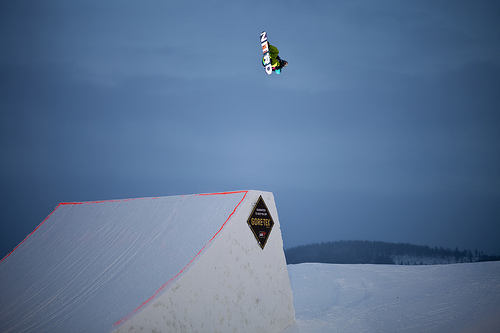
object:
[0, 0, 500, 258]
blue sky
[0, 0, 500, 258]
cloud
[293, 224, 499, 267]
trees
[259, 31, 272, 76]
snowboard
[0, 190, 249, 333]
square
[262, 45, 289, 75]
man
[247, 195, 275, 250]
sign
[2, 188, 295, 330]
ramp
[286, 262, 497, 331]
snow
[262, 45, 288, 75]
gear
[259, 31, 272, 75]
"nitro"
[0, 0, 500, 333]
air